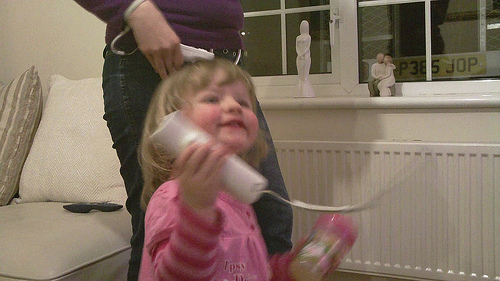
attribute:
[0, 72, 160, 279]
couch — white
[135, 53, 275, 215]
hair — blonde 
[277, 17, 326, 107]
sculpture — white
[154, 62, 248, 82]
hair — long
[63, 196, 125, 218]
remote — black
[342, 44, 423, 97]
sculpture — wooden 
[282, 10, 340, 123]
statue — white 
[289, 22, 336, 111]
statue —  white 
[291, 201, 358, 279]
cup — juice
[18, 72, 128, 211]
pillow — throw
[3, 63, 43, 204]
pillow — throw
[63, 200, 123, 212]
remote control — black 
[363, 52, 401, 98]
statuette — man and woman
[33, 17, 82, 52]
wall —  white 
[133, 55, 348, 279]
child — smiling 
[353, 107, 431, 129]
wall — striped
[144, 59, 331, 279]
girl — smiling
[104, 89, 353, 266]
controller — white 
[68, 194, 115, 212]
remote — black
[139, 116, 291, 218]
wii remote — nintendo, control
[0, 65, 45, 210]
pillow — striped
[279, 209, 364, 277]
sippy cup — pink 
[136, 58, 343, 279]
girl — small 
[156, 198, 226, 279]
stripes — light pink, dark pink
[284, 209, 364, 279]
cup — sippy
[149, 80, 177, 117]
hair — blonde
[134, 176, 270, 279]
shirt — pink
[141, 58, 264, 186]
blond girl — young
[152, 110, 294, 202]
video game — wii